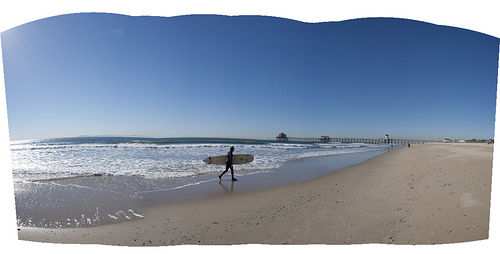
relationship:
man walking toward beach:
[215, 142, 241, 184] [205, 139, 486, 249]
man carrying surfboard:
[215, 142, 241, 184] [201, 150, 258, 167]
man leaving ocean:
[215, 142, 241, 184] [16, 133, 220, 175]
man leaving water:
[215, 142, 241, 184] [16, 133, 220, 175]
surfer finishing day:
[215, 142, 241, 184] [7, 30, 484, 238]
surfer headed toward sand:
[215, 142, 241, 184] [205, 139, 486, 249]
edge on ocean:
[284, 149, 495, 241] [16, 133, 220, 175]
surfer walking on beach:
[215, 142, 241, 184] [205, 139, 486, 249]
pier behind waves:
[273, 135, 416, 143] [23, 140, 320, 178]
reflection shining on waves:
[12, 138, 62, 176] [23, 140, 320, 178]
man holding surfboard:
[215, 142, 241, 184] [201, 150, 258, 167]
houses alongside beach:
[440, 135, 490, 145] [205, 139, 486, 249]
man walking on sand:
[215, 142, 241, 184] [205, 139, 486, 249]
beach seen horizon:
[205, 139, 486, 249] [9, 131, 247, 141]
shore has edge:
[158, 163, 490, 236] [284, 149, 495, 241]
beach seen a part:
[205, 139, 486, 249] [158, 163, 490, 236]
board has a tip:
[201, 150, 258, 167] [200, 156, 210, 164]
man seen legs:
[215, 142, 241, 184] [218, 165, 240, 184]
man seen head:
[215, 142, 241, 184] [226, 143, 240, 153]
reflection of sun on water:
[12, 138, 62, 176] [16, 133, 220, 175]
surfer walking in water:
[215, 142, 241, 184] [16, 133, 220, 175]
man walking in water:
[215, 142, 241, 184] [16, 133, 220, 175]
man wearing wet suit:
[215, 142, 241, 184] [217, 150, 239, 177]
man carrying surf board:
[215, 142, 241, 184] [201, 150, 258, 167]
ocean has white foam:
[16, 133, 220, 175] [12, 146, 188, 176]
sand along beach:
[205, 139, 486, 249] [18, 139, 481, 250]